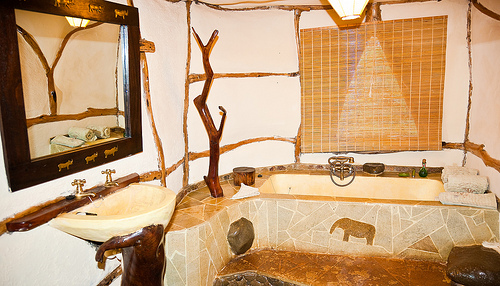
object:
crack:
[460, 0, 472, 167]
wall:
[16, 8, 495, 207]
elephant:
[329, 217, 378, 245]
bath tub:
[260, 174, 440, 201]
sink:
[53, 184, 181, 243]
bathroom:
[3, 5, 498, 283]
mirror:
[4, 0, 143, 194]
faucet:
[70, 178, 96, 198]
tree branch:
[190, 27, 225, 201]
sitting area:
[448, 244, 499, 285]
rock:
[229, 216, 254, 255]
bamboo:
[300, 14, 447, 154]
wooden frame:
[3, 136, 148, 193]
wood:
[130, 237, 168, 283]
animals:
[57, 159, 75, 170]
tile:
[428, 226, 456, 261]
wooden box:
[233, 167, 255, 186]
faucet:
[326, 155, 357, 185]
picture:
[3, 4, 494, 282]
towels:
[440, 191, 498, 209]